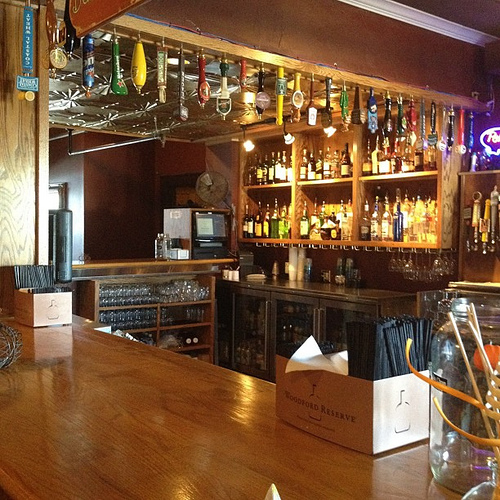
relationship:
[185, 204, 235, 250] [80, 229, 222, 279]
cash register on counter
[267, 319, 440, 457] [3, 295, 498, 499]
box on counter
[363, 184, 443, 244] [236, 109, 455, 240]
spirits on shelf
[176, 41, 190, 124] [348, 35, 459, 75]
bottle opener on ceiling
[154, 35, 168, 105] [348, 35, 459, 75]
bottle opener on ceiling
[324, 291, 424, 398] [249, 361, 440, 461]
straws in box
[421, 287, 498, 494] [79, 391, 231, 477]
jar on counter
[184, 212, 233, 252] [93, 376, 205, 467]
monitor on counter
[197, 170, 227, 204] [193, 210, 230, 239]
round fan above monitor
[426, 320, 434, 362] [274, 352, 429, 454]
straws in a box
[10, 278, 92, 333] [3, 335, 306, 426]
brown box on bar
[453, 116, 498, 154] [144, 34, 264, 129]
sign next to liquor